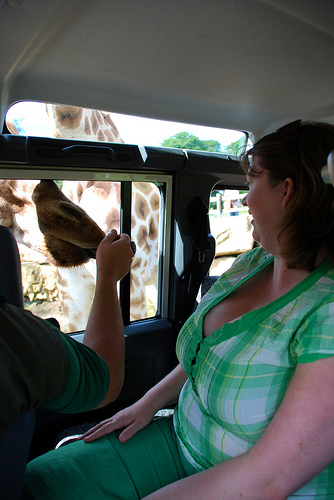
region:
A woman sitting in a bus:
[179, 113, 333, 498]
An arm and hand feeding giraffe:
[4, 236, 129, 395]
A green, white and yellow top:
[188, 282, 255, 437]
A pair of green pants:
[49, 442, 138, 477]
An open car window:
[4, 173, 165, 317]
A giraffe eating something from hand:
[29, 186, 96, 269]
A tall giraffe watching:
[42, 98, 163, 299]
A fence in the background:
[215, 190, 238, 221]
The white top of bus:
[51, 7, 274, 105]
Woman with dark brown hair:
[243, 128, 329, 261]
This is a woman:
[136, 218, 326, 353]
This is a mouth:
[41, 214, 115, 287]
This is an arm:
[50, 259, 203, 457]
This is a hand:
[106, 222, 136, 290]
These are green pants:
[53, 418, 171, 496]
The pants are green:
[33, 407, 106, 497]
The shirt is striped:
[153, 304, 325, 467]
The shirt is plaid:
[155, 381, 324, 479]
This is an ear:
[269, 196, 326, 229]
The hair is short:
[267, 224, 316, 251]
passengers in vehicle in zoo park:
[4, 90, 330, 417]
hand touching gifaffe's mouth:
[31, 182, 133, 273]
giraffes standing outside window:
[2, 96, 157, 330]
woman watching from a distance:
[121, 117, 325, 286]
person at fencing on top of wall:
[195, 179, 251, 275]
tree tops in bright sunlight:
[123, 110, 245, 159]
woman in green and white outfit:
[19, 238, 327, 490]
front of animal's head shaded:
[30, 173, 103, 267]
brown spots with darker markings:
[130, 186, 157, 248]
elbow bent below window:
[6, 323, 136, 408]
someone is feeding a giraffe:
[2, 173, 132, 412]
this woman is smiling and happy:
[237, 117, 331, 268]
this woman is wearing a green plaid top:
[167, 241, 331, 495]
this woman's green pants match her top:
[20, 411, 199, 498]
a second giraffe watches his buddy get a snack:
[36, 101, 163, 325]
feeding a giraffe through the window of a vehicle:
[3, 126, 266, 418]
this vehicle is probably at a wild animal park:
[0, 94, 333, 365]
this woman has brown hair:
[236, 116, 332, 273]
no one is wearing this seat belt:
[173, 195, 214, 332]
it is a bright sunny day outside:
[2, 97, 260, 348]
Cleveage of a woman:
[187, 294, 269, 361]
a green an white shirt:
[155, 259, 331, 473]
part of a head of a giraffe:
[1, 181, 117, 276]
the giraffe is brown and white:
[5, 183, 180, 318]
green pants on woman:
[27, 433, 215, 498]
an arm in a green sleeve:
[8, 267, 134, 412]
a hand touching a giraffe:
[73, 220, 170, 273]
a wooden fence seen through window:
[211, 190, 248, 215]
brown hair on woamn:
[234, 138, 332, 287]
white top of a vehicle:
[1, 14, 332, 152]